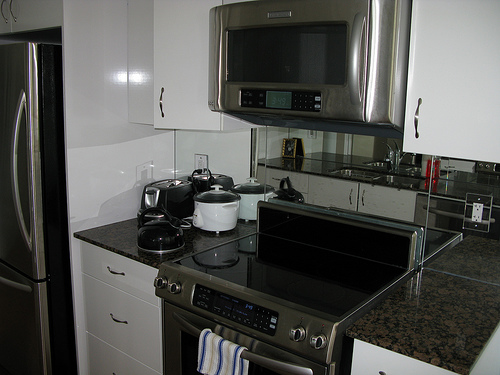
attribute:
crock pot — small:
[195, 183, 239, 233]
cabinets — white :
[151, 1, 223, 133]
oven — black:
[125, 154, 223, 236]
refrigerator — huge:
[0, 35, 70, 374]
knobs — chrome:
[151, 275, 329, 359]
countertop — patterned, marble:
[347, 234, 495, 370]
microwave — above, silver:
[209, 0, 411, 137]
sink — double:
[337, 163, 427, 188]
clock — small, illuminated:
[216, 292, 267, 341]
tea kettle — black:
[135, 201, 189, 260]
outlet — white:
[469, 200, 484, 222]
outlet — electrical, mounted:
[473, 202, 484, 222]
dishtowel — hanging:
[186, 326, 254, 374]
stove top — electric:
[167, 234, 408, 316]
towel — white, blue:
[162, 277, 272, 373]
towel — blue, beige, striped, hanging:
[185, 325, 264, 372]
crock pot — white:
[177, 178, 252, 240]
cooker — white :
[183, 179, 245, 239]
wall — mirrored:
[142, 104, 497, 373]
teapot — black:
[137, 205, 182, 251]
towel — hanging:
[194, 327, 251, 374]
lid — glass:
[194, 182, 240, 203]